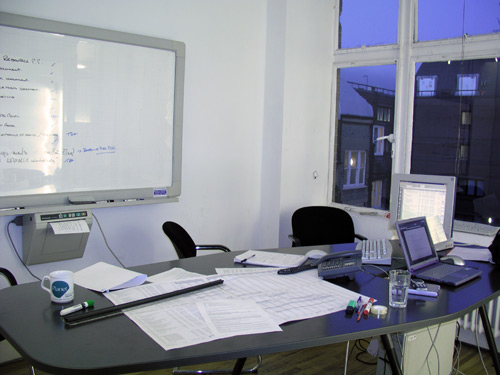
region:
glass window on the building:
[455, 75, 475, 93]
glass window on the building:
[416, 75, 432, 91]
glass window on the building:
[461, 111, 471, 121]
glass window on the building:
[456, 142, 464, 157]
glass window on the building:
[467, 175, 470, 182]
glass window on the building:
[375, 106, 390, 121]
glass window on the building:
[370, 125, 383, 155]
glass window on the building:
[371, 182, 379, 207]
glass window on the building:
[360, 150, 363, 162]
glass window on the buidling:
[338, 0, 395, 50]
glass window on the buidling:
[416, 0, 496, 40]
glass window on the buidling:
[331, 61, 393, 209]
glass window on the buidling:
[411, 60, 496, 226]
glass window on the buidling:
[456, 71, 472, 92]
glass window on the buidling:
[417, 75, 433, 95]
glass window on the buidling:
[460, 110, 470, 123]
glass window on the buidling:
[457, 143, 467, 156]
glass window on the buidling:
[373, 105, 389, 121]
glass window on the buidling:
[349, 148, 358, 187]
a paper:
[202, 300, 277, 337]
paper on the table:
[199, 293, 261, 339]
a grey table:
[88, 324, 131, 359]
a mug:
[43, 272, 80, 302]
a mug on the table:
[41, 270, 76, 302]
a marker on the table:
[58, 296, 95, 315]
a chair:
[158, 215, 202, 251]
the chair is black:
[160, 220, 196, 255]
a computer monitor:
[388, 171, 444, 215]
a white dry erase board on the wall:
[0, 15, 185, 207]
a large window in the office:
[340, 2, 496, 228]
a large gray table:
[0, 240, 492, 370]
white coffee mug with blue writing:
[40, 270, 71, 300]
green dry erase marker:
[60, 295, 94, 315]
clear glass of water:
[388, 272, 407, 309]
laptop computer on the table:
[395, 218, 478, 285]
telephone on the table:
[273, 252, 360, 279]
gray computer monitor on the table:
[392, 174, 456, 239]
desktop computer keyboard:
[353, 239, 390, 264]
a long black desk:
[17, 162, 487, 358]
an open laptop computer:
[391, 199, 494, 303]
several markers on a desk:
[340, 289, 375, 321]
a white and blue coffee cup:
[30, 260, 92, 315]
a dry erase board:
[0, 22, 222, 216]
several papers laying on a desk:
[93, 263, 383, 353]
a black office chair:
[282, 191, 395, 272]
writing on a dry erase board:
[0, 48, 82, 183]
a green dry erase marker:
[52, 294, 116, 319]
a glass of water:
[385, 263, 417, 312]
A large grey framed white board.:
[1, 10, 187, 215]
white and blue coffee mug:
[40, 269, 75, 303]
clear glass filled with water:
[388, 268, 412, 310]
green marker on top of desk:
[59, 298, 96, 317]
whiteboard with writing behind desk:
[1, 10, 187, 215]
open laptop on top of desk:
[393, 215, 484, 287]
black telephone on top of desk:
[278, 248, 364, 279]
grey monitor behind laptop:
[386, 172, 458, 243]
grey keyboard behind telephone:
[353, 237, 393, 266]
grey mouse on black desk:
[305, 249, 327, 258]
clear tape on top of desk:
[370, 303, 388, 315]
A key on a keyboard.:
[426, 267, 431, 270]